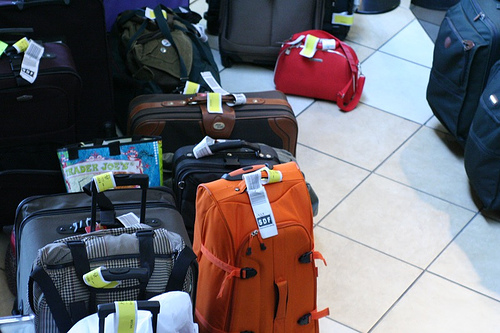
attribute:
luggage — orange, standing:
[192, 162, 329, 332]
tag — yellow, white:
[242, 171, 278, 240]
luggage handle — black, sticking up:
[91, 172, 148, 231]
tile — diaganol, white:
[1, 0, 500, 331]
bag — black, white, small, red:
[274, 28, 366, 111]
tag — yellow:
[300, 34, 319, 58]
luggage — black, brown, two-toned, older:
[127, 92, 297, 157]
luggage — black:
[464, 60, 499, 213]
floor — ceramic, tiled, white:
[0, 0, 499, 333]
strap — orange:
[200, 244, 246, 299]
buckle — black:
[239, 265, 257, 280]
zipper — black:
[17, 202, 183, 256]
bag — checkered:
[27, 224, 199, 332]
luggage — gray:
[15, 172, 192, 316]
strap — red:
[291, 29, 365, 112]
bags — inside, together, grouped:
[1, 0, 500, 332]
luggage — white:
[67, 290, 199, 332]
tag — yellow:
[207, 92, 224, 114]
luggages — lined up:
[125, 90, 330, 332]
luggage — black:
[426, 0, 499, 142]